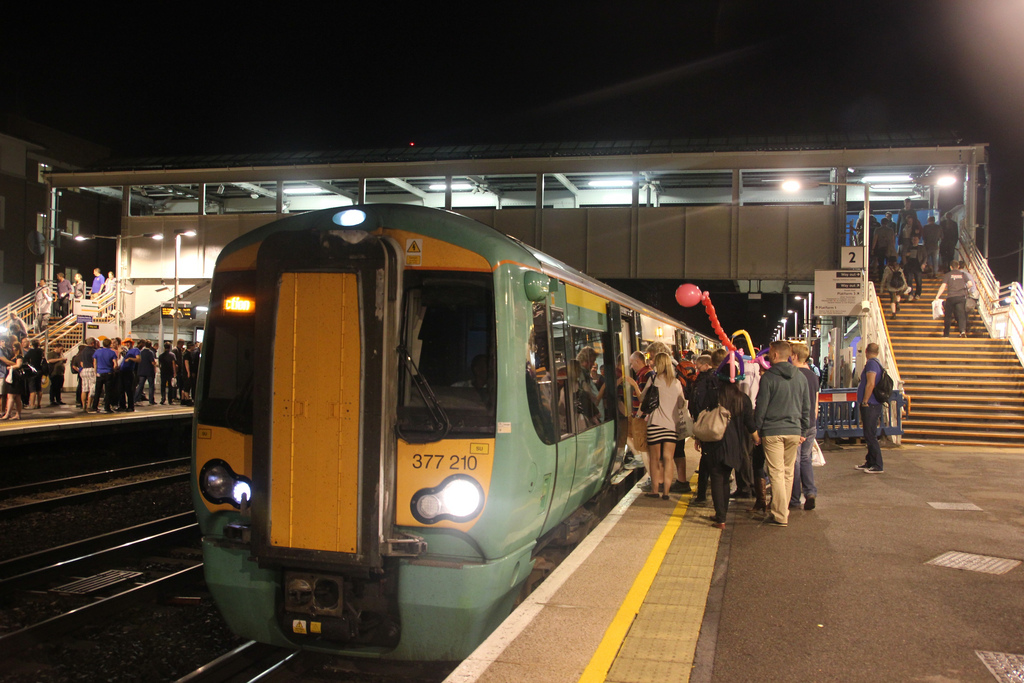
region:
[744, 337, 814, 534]
Man wearing a blue hoody.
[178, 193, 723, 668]
Green and yellow passenger train.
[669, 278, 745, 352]
Pink balloon hanging from a pink rope.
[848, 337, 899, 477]
Man carrying a backpack.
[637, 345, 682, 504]
Woman wearing a white blouse.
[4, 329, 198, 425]
People standing on a train platform.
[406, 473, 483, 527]
Black framed white headlight.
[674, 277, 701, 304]
balloon is red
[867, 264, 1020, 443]
stairs are to the right of train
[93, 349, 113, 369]
shirt is blue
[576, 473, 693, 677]
yellow line on platform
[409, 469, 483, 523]
light is lit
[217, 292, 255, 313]
orange light is lit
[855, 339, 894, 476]
man is wearing backpack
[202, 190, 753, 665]
a green and yellow train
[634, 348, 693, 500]
a woman wearing a striped skirt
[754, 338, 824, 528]
a guy wearing a hoodie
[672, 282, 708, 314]
a pink inflated balloon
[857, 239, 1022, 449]
a flight of stairs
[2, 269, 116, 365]
people walking down stairs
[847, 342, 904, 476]
a guy wearing a backpack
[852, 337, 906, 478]
a guy wearing a blue t-shirt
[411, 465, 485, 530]
headlight on a train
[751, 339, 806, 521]
A person is standing up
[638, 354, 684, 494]
A person is standing up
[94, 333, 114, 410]
A person is standing up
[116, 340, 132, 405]
A person is standing up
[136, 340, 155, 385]
A person is standing up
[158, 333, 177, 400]
A person is standing up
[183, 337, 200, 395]
A person is standing up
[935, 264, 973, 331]
A person is standing up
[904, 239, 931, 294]
A person is standing up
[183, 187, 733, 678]
electric commuter train at a loading platform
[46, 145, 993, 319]
pedestrian bridge over the train tracks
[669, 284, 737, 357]
helium filled red balloon.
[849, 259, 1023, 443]
wide stairway from platform to bridge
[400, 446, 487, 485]
number of the train car